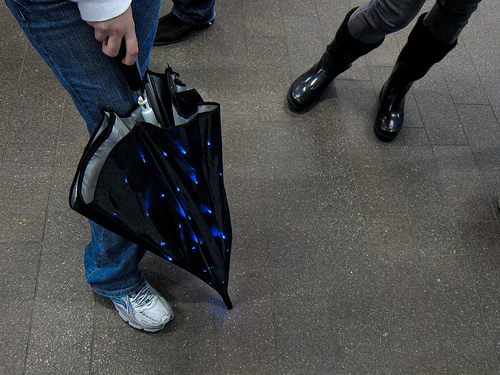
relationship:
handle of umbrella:
[106, 37, 151, 96] [59, 37, 276, 310]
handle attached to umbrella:
[106, 37, 151, 96] [59, 37, 276, 310]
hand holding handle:
[81, 12, 143, 69] [106, 37, 151, 96]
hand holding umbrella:
[81, 12, 143, 69] [59, 37, 276, 310]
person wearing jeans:
[8, 0, 242, 334] [4, 3, 188, 298]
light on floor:
[193, 237, 203, 247] [206, 300, 226, 312]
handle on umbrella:
[106, 37, 151, 96] [68, 66, 235, 311]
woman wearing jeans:
[4, 2, 229, 332] [4, 3, 188, 298]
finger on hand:
[122, 35, 140, 64] [81, 12, 143, 69]